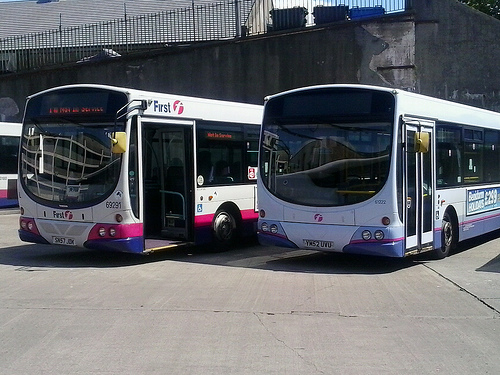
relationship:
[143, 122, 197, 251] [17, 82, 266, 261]
bus door to bus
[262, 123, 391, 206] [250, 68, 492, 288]
window of bus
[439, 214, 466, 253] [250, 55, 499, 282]
tire of bus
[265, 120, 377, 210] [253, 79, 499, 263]
window of bus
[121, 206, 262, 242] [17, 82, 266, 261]
stripe on bus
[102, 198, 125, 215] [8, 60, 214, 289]
numbers on bus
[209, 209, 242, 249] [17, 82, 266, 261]
tire on bus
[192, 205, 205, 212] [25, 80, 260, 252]
handicap sign on bus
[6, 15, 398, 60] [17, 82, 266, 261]
railing over bus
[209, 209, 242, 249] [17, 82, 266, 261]
tire of bus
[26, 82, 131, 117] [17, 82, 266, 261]
board of bus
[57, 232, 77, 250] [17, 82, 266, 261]
number plate of bus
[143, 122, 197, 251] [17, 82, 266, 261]
bus door of bus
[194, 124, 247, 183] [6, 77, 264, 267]
window of bus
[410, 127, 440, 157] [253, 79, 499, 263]
side mirror on bus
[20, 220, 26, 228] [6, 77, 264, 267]
headlight on bus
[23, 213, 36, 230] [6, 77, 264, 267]
head light on bus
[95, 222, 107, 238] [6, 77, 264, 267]
head light on bus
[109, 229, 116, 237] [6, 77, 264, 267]
headlight on bus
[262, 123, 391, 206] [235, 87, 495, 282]
window on bus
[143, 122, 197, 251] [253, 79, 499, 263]
bus door on bus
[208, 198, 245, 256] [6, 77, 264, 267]
tire on bus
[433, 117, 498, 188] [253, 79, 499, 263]
window on side of bus